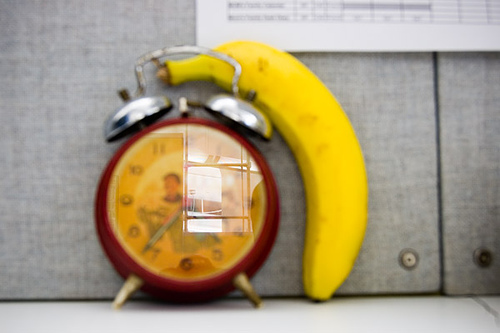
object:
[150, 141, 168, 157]
number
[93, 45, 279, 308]
clock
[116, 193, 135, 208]
number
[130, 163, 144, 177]
number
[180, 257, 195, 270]
number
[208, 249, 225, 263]
number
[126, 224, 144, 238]
number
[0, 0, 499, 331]
photo